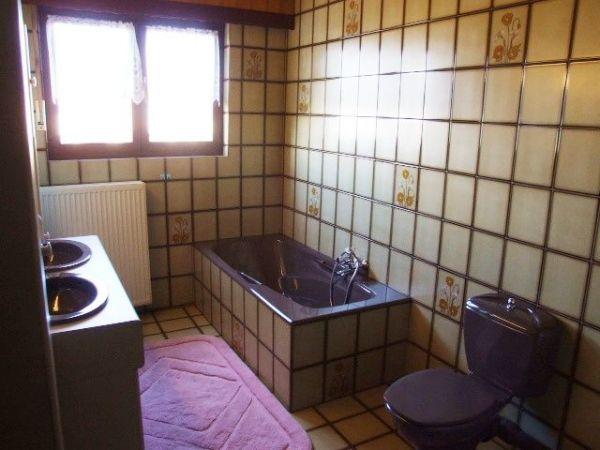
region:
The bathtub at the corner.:
[195, 242, 411, 412]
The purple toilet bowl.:
[381, 291, 560, 447]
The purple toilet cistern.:
[463, 292, 565, 390]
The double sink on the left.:
[39, 225, 142, 448]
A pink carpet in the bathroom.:
[135, 334, 309, 447]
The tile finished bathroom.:
[35, 0, 597, 448]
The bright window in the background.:
[43, 12, 223, 152]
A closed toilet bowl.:
[383, 368, 503, 448]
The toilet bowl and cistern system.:
[383, 292, 557, 447]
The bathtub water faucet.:
[327, 242, 365, 305]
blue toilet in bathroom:
[385, 283, 560, 446]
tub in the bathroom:
[184, 228, 412, 428]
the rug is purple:
[106, 322, 322, 444]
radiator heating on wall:
[34, 175, 158, 315]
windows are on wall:
[30, 7, 234, 161]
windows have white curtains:
[38, 9, 231, 149]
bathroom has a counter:
[29, 227, 161, 443]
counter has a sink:
[35, 233, 93, 271]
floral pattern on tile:
[394, 167, 418, 212]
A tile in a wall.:
[240, 174, 266, 210]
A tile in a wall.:
[164, 210, 195, 243]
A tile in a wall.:
[192, 207, 217, 236]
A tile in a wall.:
[165, 156, 189, 183]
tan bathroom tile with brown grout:
[442, 171, 478, 226]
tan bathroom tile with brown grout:
[469, 172, 514, 235]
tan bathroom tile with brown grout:
[505, 183, 553, 249]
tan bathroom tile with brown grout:
[546, 186, 596, 261]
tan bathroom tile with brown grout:
[414, 167, 446, 219]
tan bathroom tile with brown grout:
[370, 198, 393, 248]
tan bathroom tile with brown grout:
[241, 284, 258, 337]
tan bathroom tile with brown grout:
[108, 157, 139, 180]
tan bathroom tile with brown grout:
[50, 160, 83, 183]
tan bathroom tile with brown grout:
[166, 179, 192, 212]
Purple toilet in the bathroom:
[365, 272, 568, 449]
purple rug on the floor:
[141, 326, 311, 448]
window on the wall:
[39, 8, 237, 164]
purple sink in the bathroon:
[36, 215, 111, 330]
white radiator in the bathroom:
[35, 177, 153, 313]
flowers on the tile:
[391, 162, 418, 209]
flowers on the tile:
[429, 272, 465, 321]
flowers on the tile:
[296, 180, 326, 216]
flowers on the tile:
[292, 80, 311, 120]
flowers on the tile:
[243, 48, 268, 86]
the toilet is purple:
[372, 269, 573, 448]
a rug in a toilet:
[141, 330, 310, 446]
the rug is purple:
[142, 320, 315, 445]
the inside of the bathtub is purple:
[188, 213, 407, 352]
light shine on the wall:
[292, 18, 471, 172]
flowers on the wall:
[482, 7, 533, 73]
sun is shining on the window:
[34, 4, 236, 172]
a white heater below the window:
[29, 116, 168, 311]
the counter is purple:
[39, 221, 144, 335]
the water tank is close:
[457, 273, 571, 411]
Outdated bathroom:
[8, 6, 596, 446]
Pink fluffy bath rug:
[129, 335, 318, 449]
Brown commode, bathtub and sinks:
[21, 161, 593, 449]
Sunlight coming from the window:
[27, 4, 237, 159]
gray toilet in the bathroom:
[382, 291, 562, 448]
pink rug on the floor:
[139, 331, 313, 449]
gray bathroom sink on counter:
[39, 272, 106, 324]